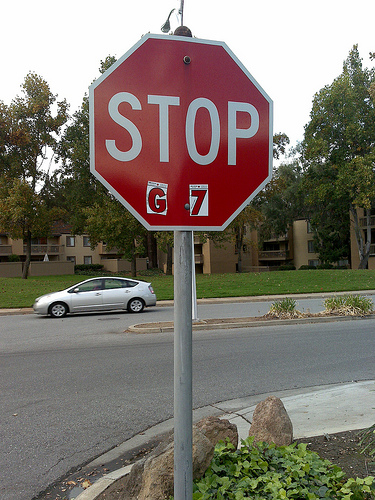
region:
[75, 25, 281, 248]
a STOP sign on corner of street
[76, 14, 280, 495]
a gray pole holding a STOP sign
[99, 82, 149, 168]
letter S on STOP sign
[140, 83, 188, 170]
letter T on STOP sign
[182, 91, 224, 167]
letter O on STOP sign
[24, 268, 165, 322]
the car is color gray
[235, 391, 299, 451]
rock on the curb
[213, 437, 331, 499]
leaves on a the ground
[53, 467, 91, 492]
leaves on the ground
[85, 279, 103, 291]
person driving the car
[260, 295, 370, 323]
bushes on the ground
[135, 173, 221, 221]
stickers on the stop sign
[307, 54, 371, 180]
leaves on a tree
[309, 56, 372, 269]
trees in front of the building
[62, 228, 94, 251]
windows on the building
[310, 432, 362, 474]
dirt near the curb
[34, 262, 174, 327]
car parked on the curb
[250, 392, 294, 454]
rocks on the curb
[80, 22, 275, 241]
stop sign on a metal pole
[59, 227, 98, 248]
windows on the apartment building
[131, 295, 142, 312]
silver rims on the car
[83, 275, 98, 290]
person driving the car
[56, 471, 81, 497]
puddle of water on the curb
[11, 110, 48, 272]
trees in the lot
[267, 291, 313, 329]
bush on the curb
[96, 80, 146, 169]
This is a letter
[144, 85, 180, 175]
This is a letter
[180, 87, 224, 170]
This is a letter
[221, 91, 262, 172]
This is a letter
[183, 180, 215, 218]
This is a number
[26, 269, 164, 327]
This is a car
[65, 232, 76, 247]
This is a window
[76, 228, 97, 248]
This is a window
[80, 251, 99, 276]
This is a window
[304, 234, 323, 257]
This is a window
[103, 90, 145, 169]
white letter on sign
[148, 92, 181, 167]
white letter on sign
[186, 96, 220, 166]
white letter on sign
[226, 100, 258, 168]
white letter on sign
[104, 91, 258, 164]
white letters on sign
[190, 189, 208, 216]
red number on sign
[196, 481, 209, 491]
green leaf on plant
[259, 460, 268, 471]
green leaf on plant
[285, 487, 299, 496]
green leaf on plant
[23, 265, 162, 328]
Silver four door car driving down road.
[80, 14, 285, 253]
Red and white stop sign.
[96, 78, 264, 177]
"STOP" written on a sign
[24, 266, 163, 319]
The side of a silver car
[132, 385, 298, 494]
Large rocks on the ground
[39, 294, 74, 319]
A black round car tire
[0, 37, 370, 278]
Green leaves on the trees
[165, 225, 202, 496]
A gray pole holding up a sign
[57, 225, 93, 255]
Two windows on building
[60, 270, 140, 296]
Windows on a car